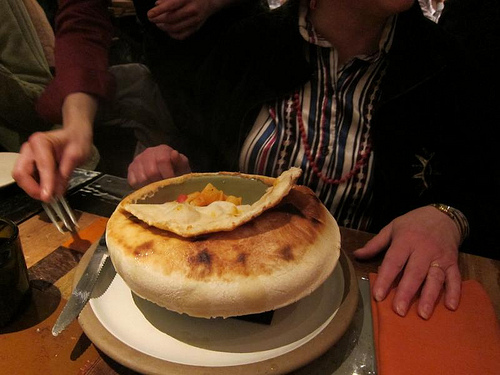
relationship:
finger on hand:
[443, 263, 461, 313] [359, 198, 470, 323]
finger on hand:
[351, 220, 392, 261] [352, 204, 462, 321]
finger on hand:
[443, 263, 461, 313] [352, 204, 462, 321]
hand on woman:
[352, 204, 462, 321] [126, 0, 500, 323]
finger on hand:
[349, 229, 386, 261] [352, 204, 462, 321]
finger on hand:
[351, 220, 392, 261] [124, 142, 191, 191]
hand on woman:
[124, 142, 191, 191] [126, 0, 500, 323]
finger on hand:
[444, 259, 462, 320] [352, 204, 462, 321]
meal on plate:
[105, 169, 345, 321] [87, 248, 331, 368]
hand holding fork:
[10, 126, 93, 205] [40, 184, 80, 234]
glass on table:
[0, 219, 40, 330] [1, 144, 498, 372]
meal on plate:
[105, 169, 345, 321] [80, 238, 353, 369]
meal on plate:
[95, 151, 350, 370] [35, 220, 467, 373]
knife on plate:
[50, 229, 107, 338] [80, 238, 353, 369]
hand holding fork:
[12, 126, 96, 202] [38, 192, 83, 237]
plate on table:
[87, 257, 349, 370] [341, 266, 479, 366]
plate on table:
[67, 219, 361, 374] [1, 144, 498, 372]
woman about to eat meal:
[127, 0, 499, 320] [105, 169, 345, 321]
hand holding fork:
[12, 126, 96, 202] [17, 168, 108, 251]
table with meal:
[292, 226, 499, 372] [105, 169, 345, 321]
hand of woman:
[352, 204, 462, 321] [127, 0, 499, 320]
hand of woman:
[124, 142, 191, 191] [127, 0, 499, 320]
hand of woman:
[353, 202, 464, 317] [127, 0, 499, 320]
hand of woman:
[352, 204, 462, 321] [51, 7, 291, 157]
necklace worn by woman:
[254, 31, 379, 187] [145, 4, 491, 309]